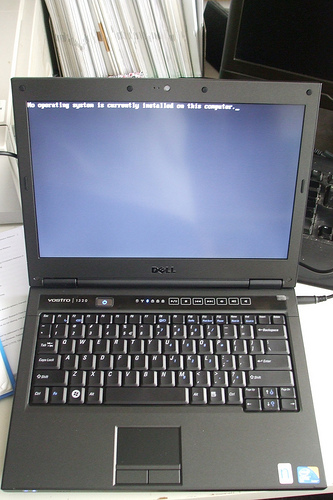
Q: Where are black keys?
A: On laptop keyboard.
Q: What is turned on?
A: Laptop screen.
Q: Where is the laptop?
A: On a table.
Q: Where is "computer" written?
A: On the screen.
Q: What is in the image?
A: Laptop.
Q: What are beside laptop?
A: Papers.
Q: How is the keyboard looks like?
A: Black.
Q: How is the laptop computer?
A: Open.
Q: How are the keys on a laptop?
A: Black and white.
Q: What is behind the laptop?
A: White paper.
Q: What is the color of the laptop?
A: Black.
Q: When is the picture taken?
A: Daytime.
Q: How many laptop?
A: 2.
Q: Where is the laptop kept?
A: Table.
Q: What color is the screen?
A: Blue.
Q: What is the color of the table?
A: White.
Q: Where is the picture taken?
A: At the office.